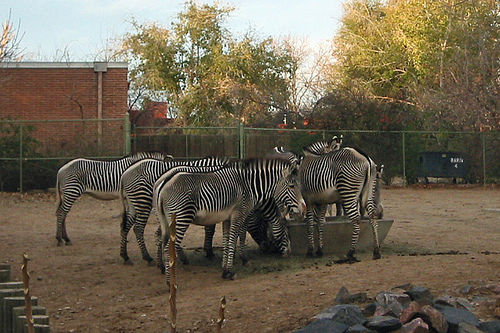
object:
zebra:
[148, 162, 268, 272]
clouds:
[0, 0, 339, 59]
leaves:
[410, 36, 412, 37]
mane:
[246, 153, 288, 162]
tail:
[155, 187, 170, 252]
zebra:
[157, 154, 307, 291]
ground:
[405, 188, 500, 278]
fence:
[0, 116, 499, 172]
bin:
[426, 148, 476, 184]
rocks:
[334, 286, 352, 303]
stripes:
[184, 206, 195, 210]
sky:
[3, 0, 329, 59]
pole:
[239, 120, 245, 159]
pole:
[401, 131, 406, 186]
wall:
[1, 64, 128, 164]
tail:
[118, 182, 130, 229]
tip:
[120, 218, 128, 235]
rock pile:
[393, 302, 451, 329]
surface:
[1, 217, 498, 310]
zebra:
[114, 155, 243, 267]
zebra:
[49, 151, 176, 245]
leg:
[228, 218, 240, 270]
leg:
[133, 208, 153, 262]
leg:
[119, 206, 132, 260]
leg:
[56, 188, 77, 241]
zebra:
[297, 134, 381, 264]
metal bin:
[275, 210, 392, 259]